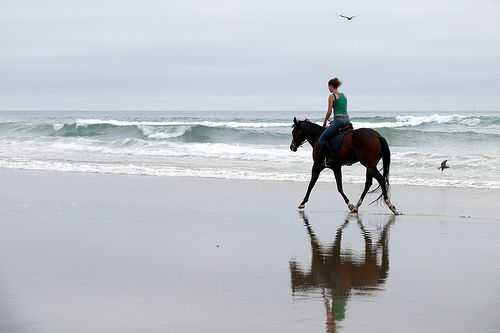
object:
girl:
[317, 75, 353, 168]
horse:
[287, 115, 404, 217]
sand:
[0, 191, 500, 305]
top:
[331, 91, 350, 117]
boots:
[316, 136, 342, 170]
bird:
[333, 6, 359, 27]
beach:
[0, 123, 500, 333]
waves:
[0, 114, 500, 190]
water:
[0, 110, 500, 191]